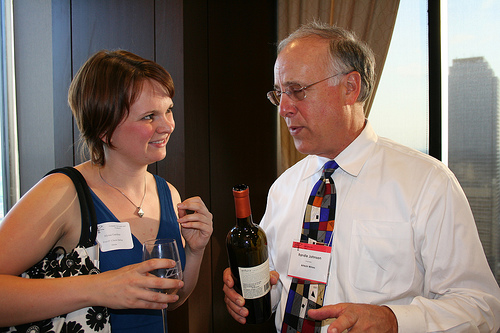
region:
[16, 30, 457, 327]
a man and woman talking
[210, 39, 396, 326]
a man holding a wine bottle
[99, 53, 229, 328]
a woman holding a wine glass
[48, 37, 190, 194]
a woman smiling at a man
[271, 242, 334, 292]
an orange and white nametag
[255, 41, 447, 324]
a man wearing a white shirt and a tir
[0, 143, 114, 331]
a person carrying a black and white flower purse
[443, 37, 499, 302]
a building out the window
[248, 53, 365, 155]
a man with his eyes closed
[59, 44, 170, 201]
a woman with short brown hair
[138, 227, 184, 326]
Wine glass in a hand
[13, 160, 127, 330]
Purse on a woman's shoulder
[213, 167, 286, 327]
Wine bottle in a hand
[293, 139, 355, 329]
Tie on a man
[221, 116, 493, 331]
White shirt on a man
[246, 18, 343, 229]
Glasses on a man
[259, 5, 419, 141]
A man with gray hair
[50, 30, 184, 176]
A woman with red hair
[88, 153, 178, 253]
Necklace on a woman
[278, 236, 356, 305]
Name tag on a man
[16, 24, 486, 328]
People drink wine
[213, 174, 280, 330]
Bottle of wine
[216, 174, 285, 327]
Bottleneck of wine is red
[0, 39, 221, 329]
Woman holds a wine cap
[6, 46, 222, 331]
Woman wears a blue dress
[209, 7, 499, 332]
Man has a long sleeve shirt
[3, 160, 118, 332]
Purse on right shoulder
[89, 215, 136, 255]
Sticker on blue dress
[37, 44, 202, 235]
Woman wears a necklace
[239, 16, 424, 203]
Man has glasses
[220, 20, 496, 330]
Man holding a wine bottle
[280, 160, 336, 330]
Colorful tie worn by a man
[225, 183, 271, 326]
Bottle of wine held by a man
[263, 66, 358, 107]
Eyeglasses worn by a man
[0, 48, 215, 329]
Woman holding a wine glass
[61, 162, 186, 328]
Blue top worn by a woman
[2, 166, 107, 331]
White, brown flowered woman's purse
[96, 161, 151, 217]
Silver necklace worn by a woman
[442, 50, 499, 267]
Skyscraper in the background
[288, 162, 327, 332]
Man wearing a multi-colored tie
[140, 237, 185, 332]
Empty wine glass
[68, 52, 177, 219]
Woman is wearing a necklace with a charm on it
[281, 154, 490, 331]
Long-sleeved white button down shirt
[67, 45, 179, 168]
Woman has red hair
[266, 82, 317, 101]
Man wearing eyeglasses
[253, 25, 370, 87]
Man with receding hairline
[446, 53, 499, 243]
Skyscraper seen through window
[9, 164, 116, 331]
Woman has her purse straps on her right shouder